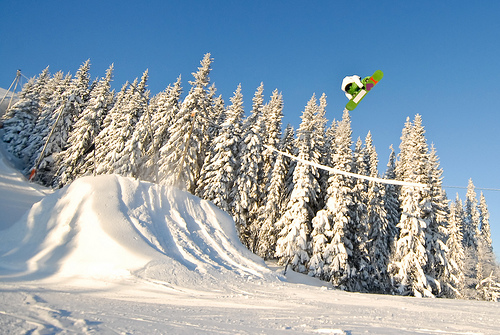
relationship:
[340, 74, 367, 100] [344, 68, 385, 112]
person on a snowboard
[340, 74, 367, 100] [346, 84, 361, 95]
person wearing helmet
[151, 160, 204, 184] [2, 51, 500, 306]
snow covered trees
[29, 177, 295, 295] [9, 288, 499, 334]
ramp made of snow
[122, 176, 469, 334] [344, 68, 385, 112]
tracks of snowboard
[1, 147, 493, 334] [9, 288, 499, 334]
ground covered with snow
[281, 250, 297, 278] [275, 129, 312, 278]
trunk of a tree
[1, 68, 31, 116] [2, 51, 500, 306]
pole behind trees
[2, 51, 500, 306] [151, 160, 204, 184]
trees covered with snow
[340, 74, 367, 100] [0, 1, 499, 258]
person in sky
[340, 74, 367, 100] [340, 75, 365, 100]
person wearing white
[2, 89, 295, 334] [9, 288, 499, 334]
hill of snow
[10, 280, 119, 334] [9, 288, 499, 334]
lines in snow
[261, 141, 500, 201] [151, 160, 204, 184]
wire covered in snow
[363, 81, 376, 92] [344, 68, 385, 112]
heart on snowboard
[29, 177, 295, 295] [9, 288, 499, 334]
ramp of snow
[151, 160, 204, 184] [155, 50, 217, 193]
snow covered tree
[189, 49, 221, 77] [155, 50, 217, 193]
top of tree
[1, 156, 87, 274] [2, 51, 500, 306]
shadows of trees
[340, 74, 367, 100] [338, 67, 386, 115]
person doing a trick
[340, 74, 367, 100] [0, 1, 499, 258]
person high in sky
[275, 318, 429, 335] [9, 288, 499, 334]
indents in snow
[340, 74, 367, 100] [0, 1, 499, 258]
person flying in sky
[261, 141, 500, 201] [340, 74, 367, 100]
wire under person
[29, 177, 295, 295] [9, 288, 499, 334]
ramp formed of snow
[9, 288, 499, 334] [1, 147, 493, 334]
snow on slope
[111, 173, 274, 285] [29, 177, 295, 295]
impressions on ramp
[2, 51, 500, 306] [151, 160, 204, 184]
trees covered in snow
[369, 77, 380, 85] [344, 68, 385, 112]
letter on snowboard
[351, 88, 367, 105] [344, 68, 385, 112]
space on snowboard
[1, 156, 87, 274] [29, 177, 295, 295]
shadows on side of ramp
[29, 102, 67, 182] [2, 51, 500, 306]
pole along trees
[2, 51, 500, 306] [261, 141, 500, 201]
trees supporting rope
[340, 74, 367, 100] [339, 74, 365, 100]
person in jacket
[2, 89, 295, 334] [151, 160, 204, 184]
hill on snow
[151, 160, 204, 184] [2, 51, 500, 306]
snow covering trees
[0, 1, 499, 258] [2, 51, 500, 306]
sky above trees